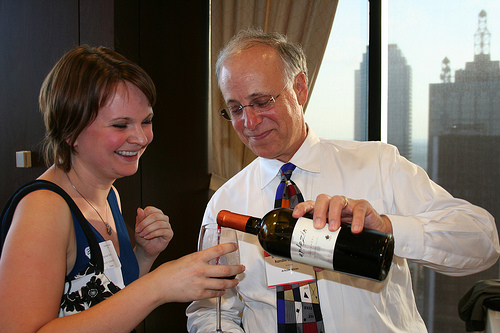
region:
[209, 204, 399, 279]
a bottle of wine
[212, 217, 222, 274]
a stream of wine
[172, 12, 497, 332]
this man is holding the bottle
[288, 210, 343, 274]
the label on the bottle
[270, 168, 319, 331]
this is the man's tie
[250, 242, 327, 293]
a nametag on his tie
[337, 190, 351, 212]
this is the man's wedding ring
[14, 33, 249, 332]
the woman is holding a wine glass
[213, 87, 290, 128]
these are glasses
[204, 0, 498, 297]
a large window and a curtain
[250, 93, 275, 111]
eye of the man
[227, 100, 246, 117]
eye of the man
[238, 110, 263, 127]
nose of the man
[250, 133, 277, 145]
mouth of the man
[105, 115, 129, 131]
eye of the woman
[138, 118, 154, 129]
eye of the woman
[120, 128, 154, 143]
nose of the woman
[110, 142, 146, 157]
mouth of the woman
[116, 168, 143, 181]
chin of the woman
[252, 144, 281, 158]
chin of the man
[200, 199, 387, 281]
bottle of red wine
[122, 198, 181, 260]
hand of a woman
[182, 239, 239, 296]
hand of the woman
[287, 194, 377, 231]
hand of the woman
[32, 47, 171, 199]
head of the woman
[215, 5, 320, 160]
head of the woman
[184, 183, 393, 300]
bottle of wine in hand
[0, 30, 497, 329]
Man pouring wine into woman's glass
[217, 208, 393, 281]
Bottle of red wine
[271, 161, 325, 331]
Multi-colored tie around man's neck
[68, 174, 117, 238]
Necklace around woman's neck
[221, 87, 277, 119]
Glasses over man's eyes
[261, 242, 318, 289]
Name tag on man's shirt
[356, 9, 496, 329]
Buildings seen outside the window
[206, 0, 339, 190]
Draperies on the window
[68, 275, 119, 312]
Flowers on woman's dress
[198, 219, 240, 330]
Wine glass in woman's hand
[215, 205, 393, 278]
the bottle of wine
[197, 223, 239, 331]
the glass under the bottle of wine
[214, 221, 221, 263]
the stream of wine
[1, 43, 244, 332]
the woman holding the wine glass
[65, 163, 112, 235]
the necklace on the woman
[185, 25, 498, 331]
the man pouring the wine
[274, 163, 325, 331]
the tie on the man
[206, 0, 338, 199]
the curtain behind the man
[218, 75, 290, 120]
the glasses on the man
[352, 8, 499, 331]
the buildings in the distance